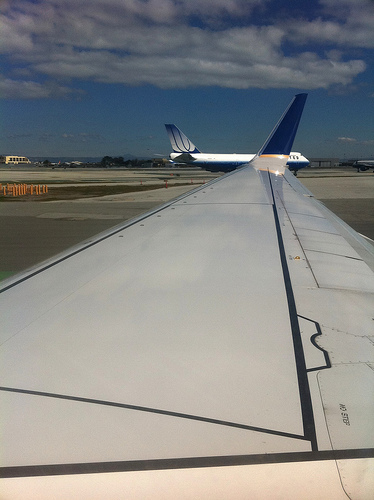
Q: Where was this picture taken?
A: The airport.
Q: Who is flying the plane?
A: The pilot.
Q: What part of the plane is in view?
A: The wing.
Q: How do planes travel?
A: They fly.